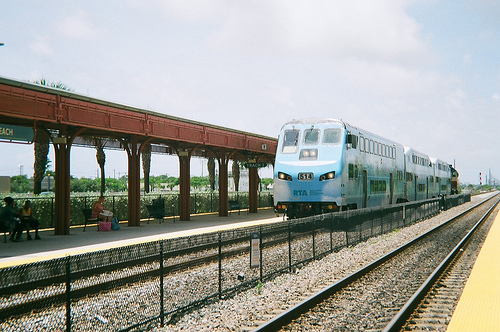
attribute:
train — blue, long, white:
[270, 115, 459, 219]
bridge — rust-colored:
[0, 74, 280, 156]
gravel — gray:
[1, 188, 499, 330]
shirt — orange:
[22, 205, 32, 218]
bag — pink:
[100, 221, 114, 231]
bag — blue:
[113, 216, 120, 230]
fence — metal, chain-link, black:
[2, 191, 276, 231]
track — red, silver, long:
[0, 188, 499, 331]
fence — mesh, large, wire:
[3, 191, 476, 331]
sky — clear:
[1, 3, 499, 176]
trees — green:
[11, 72, 274, 194]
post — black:
[217, 230, 225, 299]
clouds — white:
[2, 4, 492, 184]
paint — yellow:
[0, 245, 77, 275]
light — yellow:
[329, 171, 334, 180]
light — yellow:
[278, 171, 284, 179]